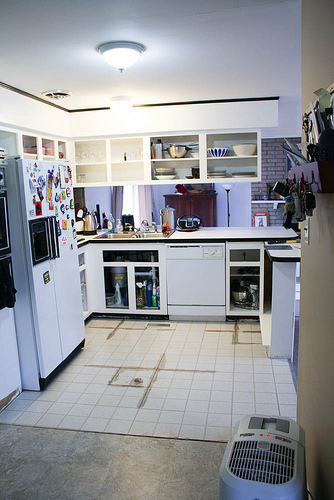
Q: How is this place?
A: The kitchen.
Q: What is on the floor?
A: Tile.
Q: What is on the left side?
A: The fridge.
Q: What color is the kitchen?
A: White.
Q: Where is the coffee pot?
A: On the kitchen counter.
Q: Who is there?
A: Nobody.